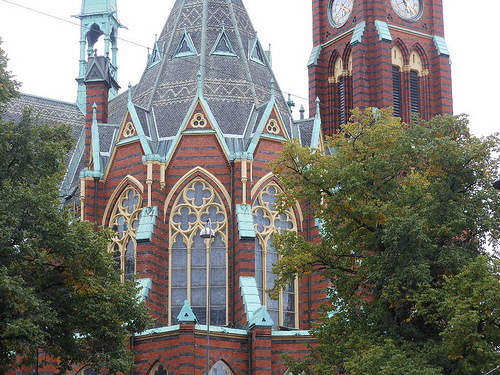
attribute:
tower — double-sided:
[306, 10, 469, 150]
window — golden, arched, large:
[156, 166, 230, 323]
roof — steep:
[49, 103, 326, 148]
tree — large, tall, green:
[284, 108, 498, 364]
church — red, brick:
[16, 4, 310, 375]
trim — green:
[111, 97, 326, 142]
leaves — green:
[302, 110, 484, 217]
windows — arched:
[98, 166, 312, 338]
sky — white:
[11, 15, 77, 88]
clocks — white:
[322, 1, 431, 28]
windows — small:
[116, 116, 282, 135]